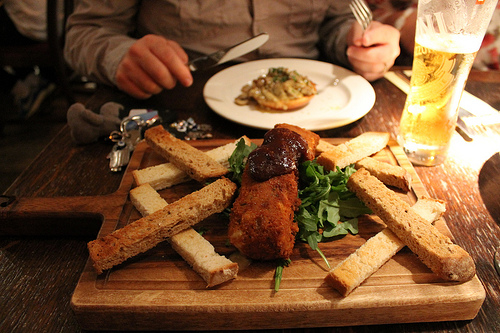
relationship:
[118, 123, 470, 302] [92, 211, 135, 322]
board has edge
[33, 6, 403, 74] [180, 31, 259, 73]
person holds knife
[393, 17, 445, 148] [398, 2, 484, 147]
beer in glass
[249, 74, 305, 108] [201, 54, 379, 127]
food on plate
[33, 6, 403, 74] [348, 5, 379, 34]
person holds fork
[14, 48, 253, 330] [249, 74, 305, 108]
table under food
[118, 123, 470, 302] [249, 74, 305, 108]
tray under food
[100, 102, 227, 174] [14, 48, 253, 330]
keys on table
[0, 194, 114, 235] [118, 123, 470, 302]
handle on board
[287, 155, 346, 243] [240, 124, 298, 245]
lettuce under meat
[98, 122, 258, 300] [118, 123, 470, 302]
breadsticks on board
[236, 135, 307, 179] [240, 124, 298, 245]
sauce on meat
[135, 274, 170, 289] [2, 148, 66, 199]
part of a line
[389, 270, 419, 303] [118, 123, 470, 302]
part of a board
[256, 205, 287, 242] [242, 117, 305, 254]
part of a cake